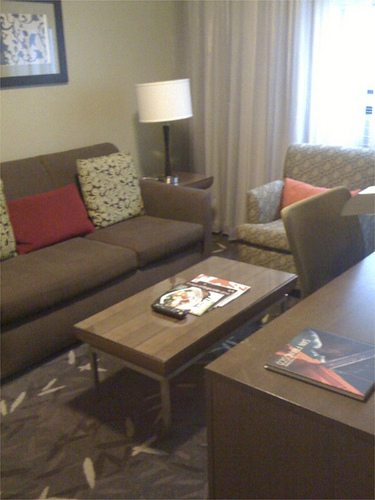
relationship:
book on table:
[127, 271, 224, 323] [59, 242, 275, 422]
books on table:
[154, 277, 252, 333] [59, 242, 275, 422]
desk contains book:
[196, 261, 374, 492] [285, 318, 368, 401]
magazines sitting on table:
[169, 275, 243, 313] [59, 242, 275, 422]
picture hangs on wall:
[10, 8, 76, 111] [7, 3, 186, 158]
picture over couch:
[10, 8, 76, 111] [6, 128, 201, 355]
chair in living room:
[245, 158, 372, 306] [4, 8, 368, 498]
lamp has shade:
[136, 76, 195, 189] [134, 78, 196, 124]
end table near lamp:
[144, 158, 227, 211] [136, 76, 195, 189]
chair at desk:
[245, 158, 372, 306] [196, 261, 374, 492]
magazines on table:
[169, 275, 243, 313] [59, 242, 275, 422]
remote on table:
[156, 298, 187, 323] [59, 242, 275, 422]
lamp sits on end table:
[136, 76, 195, 189] [144, 158, 227, 211]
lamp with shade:
[136, 76, 195, 189] [134, 78, 196, 124]